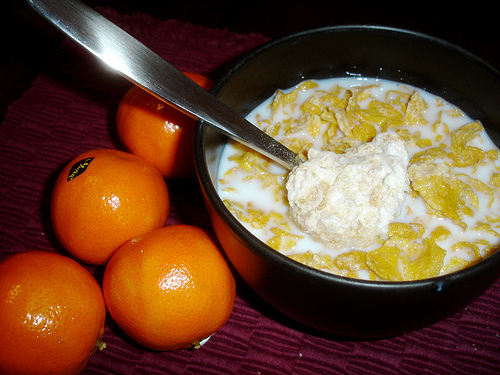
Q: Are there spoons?
A: Yes, there is a spoon.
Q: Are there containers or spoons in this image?
A: Yes, there is a spoon.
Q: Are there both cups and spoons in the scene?
A: No, there is a spoon but no cups.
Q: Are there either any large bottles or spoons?
A: Yes, there is a large spoon.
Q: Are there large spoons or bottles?
A: Yes, there is a large spoon.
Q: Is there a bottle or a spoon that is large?
A: Yes, the spoon is large.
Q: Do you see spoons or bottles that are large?
A: Yes, the spoon is large.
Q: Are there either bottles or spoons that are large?
A: Yes, the spoon is large.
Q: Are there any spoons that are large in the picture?
A: Yes, there is a large spoon.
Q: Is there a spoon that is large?
A: Yes, there is a spoon that is large.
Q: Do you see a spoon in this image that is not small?
A: Yes, there is a large spoon.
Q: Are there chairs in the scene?
A: No, there are no chairs.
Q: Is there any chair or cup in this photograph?
A: No, there are no chairs or cups.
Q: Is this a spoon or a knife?
A: This is a spoon.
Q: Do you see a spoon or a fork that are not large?
A: No, there is a spoon but it is large.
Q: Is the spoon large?
A: Yes, the spoon is large.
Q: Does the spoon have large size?
A: Yes, the spoon is large.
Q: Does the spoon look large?
A: Yes, the spoon is large.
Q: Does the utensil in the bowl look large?
A: Yes, the spoon is large.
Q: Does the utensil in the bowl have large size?
A: Yes, the spoon is large.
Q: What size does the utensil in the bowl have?
A: The spoon has large size.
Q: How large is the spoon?
A: The spoon is large.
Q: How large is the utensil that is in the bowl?
A: The spoon is large.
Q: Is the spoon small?
A: No, the spoon is large.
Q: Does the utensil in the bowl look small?
A: No, the spoon is large.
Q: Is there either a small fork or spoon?
A: No, there is a spoon but it is large.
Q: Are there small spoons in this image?
A: No, there is a spoon but it is large.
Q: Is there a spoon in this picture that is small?
A: No, there is a spoon but it is large.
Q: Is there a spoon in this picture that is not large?
A: No, there is a spoon but it is large.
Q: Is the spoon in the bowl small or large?
A: The spoon is large.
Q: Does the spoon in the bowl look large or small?
A: The spoon is large.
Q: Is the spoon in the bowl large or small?
A: The spoon is large.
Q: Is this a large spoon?
A: Yes, this is a large spoon.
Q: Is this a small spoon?
A: No, this is a large spoon.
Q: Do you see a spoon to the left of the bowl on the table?
A: Yes, there is a spoon to the left of the bowl.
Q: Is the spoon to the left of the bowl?
A: Yes, the spoon is to the left of the bowl.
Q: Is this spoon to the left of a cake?
A: No, the spoon is to the left of the bowl.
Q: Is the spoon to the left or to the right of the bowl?
A: The spoon is to the left of the bowl.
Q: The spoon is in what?
A: The spoon is in the bowl.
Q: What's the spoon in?
A: The spoon is in the bowl.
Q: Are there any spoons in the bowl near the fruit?
A: Yes, there is a spoon in the bowl.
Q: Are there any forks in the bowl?
A: No, there is a spoon in the bowl.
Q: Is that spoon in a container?
A: No, the spoon is in the bowl.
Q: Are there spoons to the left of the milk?
A: Yes, there is a spoon to the left of the milk.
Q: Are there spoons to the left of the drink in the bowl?
A: Yes, there is a spoon to the left of the milk.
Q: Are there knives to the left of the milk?
A: No, there is a spoon to the left of the milk.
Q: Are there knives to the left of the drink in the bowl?
A: No, there is a spoon to the left of the milk.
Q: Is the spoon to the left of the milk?
A: Yes, the spoon is to the left of the milk.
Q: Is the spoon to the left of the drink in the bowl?
A: Yes, the spoon is to the left of the milk.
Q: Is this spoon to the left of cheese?
A: No, the spoon is to the left of the milk.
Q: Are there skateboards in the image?
A: No, there are no skateboards.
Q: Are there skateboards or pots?
A: No, there are no skateboards or pots.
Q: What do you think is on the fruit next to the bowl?
A: The sticker is on the fruit.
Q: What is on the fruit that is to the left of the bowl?
A: The sticker is on the fruit.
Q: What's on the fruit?
A: The sticker is on the fruit.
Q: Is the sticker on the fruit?
A: Yes, the sticker is on the fruit.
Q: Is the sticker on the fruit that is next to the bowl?
A: Yes, the sticker is on the fruit.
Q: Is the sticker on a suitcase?
A: No, the sticker is on the fruit.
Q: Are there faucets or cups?
A: No, there are no cups or faucets.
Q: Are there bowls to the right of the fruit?
A: Yes, there is a bowl to the right of the fruit.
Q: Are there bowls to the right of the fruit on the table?
A: Yes, there is a bowl to the right of the fruit.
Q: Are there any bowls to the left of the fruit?
A: No, the bowl is to the right of the fruit.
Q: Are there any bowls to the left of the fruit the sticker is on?
A: No, the bowl is to the right of the fruit.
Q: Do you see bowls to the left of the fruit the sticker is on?
A: No, the bowl is to the right of the fruit.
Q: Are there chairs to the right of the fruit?
A: No, there is a bowl to the right of the fruit.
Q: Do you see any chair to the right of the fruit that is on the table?
A: No, there is a bowl to the right of the fruit.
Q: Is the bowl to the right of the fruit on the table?
A: Yes, the bowl is to the right of the fruit.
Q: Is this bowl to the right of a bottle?
A: No, the bowl is to the right of the fruit.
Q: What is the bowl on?
A: The bowl is on the table.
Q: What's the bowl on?
A: The bowl is on the table.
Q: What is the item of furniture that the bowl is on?
A: The piece of furniture is a table.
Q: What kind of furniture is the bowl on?
A: The bowl is on the table.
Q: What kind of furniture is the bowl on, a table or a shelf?
A: The bowl is on a table.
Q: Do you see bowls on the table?
A: Yes, there is a bowl on the table.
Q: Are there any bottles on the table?
A: No, there is a bowl on the table.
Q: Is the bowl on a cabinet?
A: No, the bowl is on a table.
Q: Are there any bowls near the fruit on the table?
A: Yes, there is a bowl near the fruit.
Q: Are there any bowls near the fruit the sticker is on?
A: Yes, there is a bowl near the fruit.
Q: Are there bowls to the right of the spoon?
A: Yes, there is a bowl to the right of the spoon.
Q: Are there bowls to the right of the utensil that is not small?
A: Yes, there is a bowl to the right of the spoon.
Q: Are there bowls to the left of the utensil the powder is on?
A: No, the bowl is to the right of the spoon.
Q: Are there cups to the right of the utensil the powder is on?
A: No, there is a bowl to the right of the spoon.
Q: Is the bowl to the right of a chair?
A: No, the bowl is to the right of the spoon.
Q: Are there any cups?
A: No, there are no cups.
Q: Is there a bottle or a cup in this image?
A: No, there are no cups or bottles.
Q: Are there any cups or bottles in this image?
A: No, there are no cups or bottles.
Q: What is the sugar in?
A: The sugar is in the bowl.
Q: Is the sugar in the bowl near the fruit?
A: Yes, the sugar is in the bowl.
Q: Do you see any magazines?
A: No, there are no magazines.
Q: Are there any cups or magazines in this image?
A: No, there are no magazines or cups.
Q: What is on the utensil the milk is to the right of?
A: The powder is on the spoon.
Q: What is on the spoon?
A: The powder is on the spoon.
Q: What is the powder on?
A: The powder is on the spoon.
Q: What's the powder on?
A: The powder is on the spoon.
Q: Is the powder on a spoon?
A: Yes, the powder is on a spoon.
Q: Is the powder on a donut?
A: No, the powder is on a spoon.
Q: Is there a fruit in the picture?
A: Yes, there is a fruit.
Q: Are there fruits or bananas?
A: Yes, there is a fruit.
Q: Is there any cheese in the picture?
A: No, there is no cheese.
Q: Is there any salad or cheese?
A: No, there are no cheese or salad.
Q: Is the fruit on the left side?
A: Yes, the fruit is on the left of the image.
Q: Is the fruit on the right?
A: No, the fruit is on the left of the image.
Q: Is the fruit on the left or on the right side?
A: The fruit is on the left of the image.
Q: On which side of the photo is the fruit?
A: The fruit is on the left of the image.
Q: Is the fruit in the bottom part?
A: Yes, the fruit is in the bottom of the image.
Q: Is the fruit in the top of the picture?
A: No, the fruit is in the bottom of the image.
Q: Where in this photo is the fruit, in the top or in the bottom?
A: The fruit is in the bottom of the image.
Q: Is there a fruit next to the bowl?
A: Yes, there is a fruit next to the bowl.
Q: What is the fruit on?
A: The fruit is on the table.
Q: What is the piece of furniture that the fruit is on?
A: The piece of furniture is a table.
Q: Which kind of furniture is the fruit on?
A: The fruit is on the table.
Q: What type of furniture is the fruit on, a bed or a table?
A: The fruit is on a table.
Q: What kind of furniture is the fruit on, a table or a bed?
A: The fruit is on a table.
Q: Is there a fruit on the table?
A: Yes, there is a fruit on the table.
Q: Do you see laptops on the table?
A: No, there is a fruit on the table.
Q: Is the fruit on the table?
A: Yes, the fruit is on the table.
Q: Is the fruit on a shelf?
A: No, the fruit is on the table.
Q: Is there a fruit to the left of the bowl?
A: Yes, there is a fruit to the left of the bowl.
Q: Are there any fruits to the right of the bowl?
A: No, the fruit is to the left of the bowl.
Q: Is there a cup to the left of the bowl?
A: No, there is a fruit to the left of the bowl.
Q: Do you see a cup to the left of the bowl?
A: No, there is a fruit to the left of the bowl.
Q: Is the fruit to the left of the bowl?
A: Yes, the fruit is to the left of the bowl.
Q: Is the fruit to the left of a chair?
A: No, the fruit is to the left of the bowl.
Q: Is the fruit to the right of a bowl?
A: No, the fruit is to the left of a bowl.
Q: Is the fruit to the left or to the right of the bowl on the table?
A: The fruit is to the left of the bowl.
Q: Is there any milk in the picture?
A: Yes, there is milk.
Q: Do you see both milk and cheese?
A: No, there is milk but no cheese.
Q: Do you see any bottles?
A: No, there are no bottles.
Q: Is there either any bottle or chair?
A: No, there are no bottles or chairs.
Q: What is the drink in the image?
A: The drink is milk.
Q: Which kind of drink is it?
A: The drink is milk.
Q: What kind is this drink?
A: That is milk.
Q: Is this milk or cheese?
A: This is milk.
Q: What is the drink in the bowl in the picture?
A: The drink is milk.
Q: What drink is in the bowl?
A: The drink is milk.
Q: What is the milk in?
A: The milk is in the bowl.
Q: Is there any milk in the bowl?
A: Yes, there is milk in the bowl.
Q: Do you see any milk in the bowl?
A: Yes, there is milk in the bowl.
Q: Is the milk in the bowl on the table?
A: Yes, the milk is in the bowl.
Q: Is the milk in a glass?
A: No, the milk is in the bowl.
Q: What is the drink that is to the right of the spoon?
A: The drink is milk.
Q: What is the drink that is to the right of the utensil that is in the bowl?
A: The drink is milk.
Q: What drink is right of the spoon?
A: The drink is milk.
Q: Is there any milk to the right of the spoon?
A: Yes, there is milk to the right of the spoon.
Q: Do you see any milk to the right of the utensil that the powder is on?
A: Yes, there is milk to the right of the spoon.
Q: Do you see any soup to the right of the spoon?
A: No, there is milk to the right of the spoon.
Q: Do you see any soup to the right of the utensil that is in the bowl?
A: No, there is milk to the right of the spoon.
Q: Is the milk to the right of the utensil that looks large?
A: Yes, the milk is to the right of the spoon.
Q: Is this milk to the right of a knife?
A: No, the milk is to the right of the spoon.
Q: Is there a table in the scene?
A: Yes, there is a table.